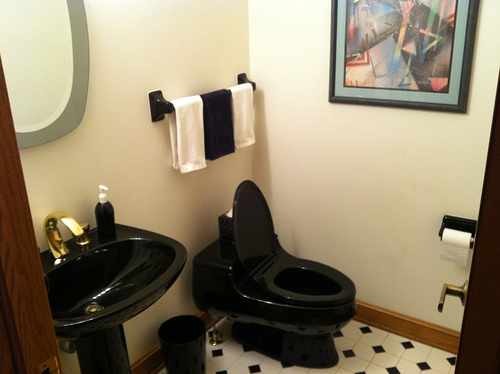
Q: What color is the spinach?
A: Green.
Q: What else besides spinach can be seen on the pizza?
A: Pepperoni.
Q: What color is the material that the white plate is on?
A: Grey.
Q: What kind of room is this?
A: A bathroom.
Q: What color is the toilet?
A: Black.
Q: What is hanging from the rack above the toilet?
A: Towels.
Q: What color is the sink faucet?
A: Gold.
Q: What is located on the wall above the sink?
A: A mirror.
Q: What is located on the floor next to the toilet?
A: A trash can.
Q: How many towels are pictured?
A: Three.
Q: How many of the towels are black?
A: One.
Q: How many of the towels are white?
A: Two.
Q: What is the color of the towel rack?
A: Black.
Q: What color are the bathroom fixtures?
A: Black.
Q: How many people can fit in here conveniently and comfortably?
A: One.